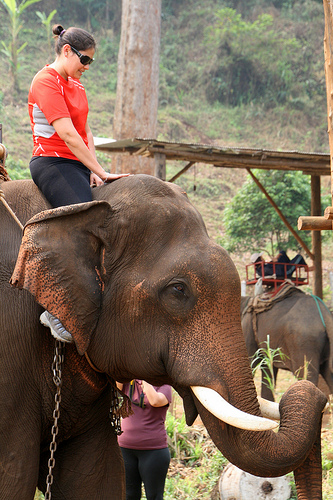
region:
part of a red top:
[56, 87, 79, 109]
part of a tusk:
[232, 407, 268, 429]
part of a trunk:
[246, 443, 284, 471]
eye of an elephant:
[159, 274, 186, 302]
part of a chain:
[34, 441, 57, 471]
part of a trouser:
[143, 449, 162, 474]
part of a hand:
[98, 161, 119, 184]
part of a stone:
[230, 472, 248, 496]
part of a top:
[137, 415, 162, 429]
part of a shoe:
[50, 309, 69, 338]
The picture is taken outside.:
[9, 7, 331, 352]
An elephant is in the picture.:
[5, 240, 306, 480]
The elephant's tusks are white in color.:
[160, 352, 285, 451]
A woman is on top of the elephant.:
[14, 17, 136, 218]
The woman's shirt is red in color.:
[10, 67, 117, 166]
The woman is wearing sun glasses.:
[50, 23, 121, 84]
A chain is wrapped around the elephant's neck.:
[22, 313, 82, 491]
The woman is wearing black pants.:
[28, 149, 92, 231]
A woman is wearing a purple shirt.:
[119, 387, 175, 448]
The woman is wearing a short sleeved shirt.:
[122, 371, 164, 444]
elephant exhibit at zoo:
[0, 0, 332, 499]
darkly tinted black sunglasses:
[69, 42, 95, 62]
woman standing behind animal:
[116, 378, 174, 499]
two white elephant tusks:
[189, 384, 281, 430]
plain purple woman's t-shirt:
[115, 383, 171, 450]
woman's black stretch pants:
[118, 446, 171, 499]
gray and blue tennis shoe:
[38, 309, 74, 342]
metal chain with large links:
[44, 339, 64, 499]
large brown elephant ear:
[8, 199, 114, 356]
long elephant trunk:
[190, 318, 327, 499]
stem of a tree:
[118, 62, 158, 120]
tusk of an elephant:
[242, 421, 277, 431]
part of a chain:
[35, 419, 69, 469]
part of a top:
[131, 418, 160, 457]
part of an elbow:
[149, 399, 163, 416]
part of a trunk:
[264, 450, 297, 479]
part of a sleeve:
[157, 377, 177, 407]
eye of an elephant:
[163, 284, 191, 305]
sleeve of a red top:
[44, 103, 71, 125]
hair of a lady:
[64, 19, 83, 47]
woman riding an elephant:
[10, 4, 258, 402]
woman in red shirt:
[11, 0, 140, 193]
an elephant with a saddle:
[198, 216, 332, 382]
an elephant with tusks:
[18, 187, 318, 462]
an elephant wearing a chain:
[10, 176, 305, 497]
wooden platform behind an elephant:
[21, 22, 332, 382]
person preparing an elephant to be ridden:
[53, 151, 264, 498]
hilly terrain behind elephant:
[6, 0, 332, 291]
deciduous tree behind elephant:
[200, 146, 331, 333]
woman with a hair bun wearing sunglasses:
[11, 13, 129, 168]